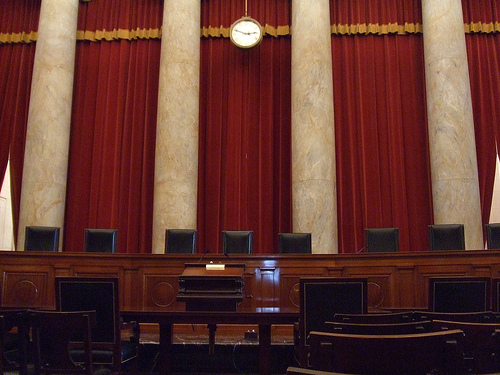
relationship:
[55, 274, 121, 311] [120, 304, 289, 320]
chair near desk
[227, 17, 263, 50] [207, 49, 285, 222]
clock in front of curtain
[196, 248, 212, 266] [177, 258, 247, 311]
microphone on top of podium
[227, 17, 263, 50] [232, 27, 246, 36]
clock has clock hand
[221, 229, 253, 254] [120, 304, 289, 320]
chair behind desk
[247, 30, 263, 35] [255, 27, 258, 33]
clock hand pointing at 2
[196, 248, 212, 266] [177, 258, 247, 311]
microphone attached to podium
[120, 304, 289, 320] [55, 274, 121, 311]
table in front of chair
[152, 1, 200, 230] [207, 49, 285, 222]
pillar in front of curtain